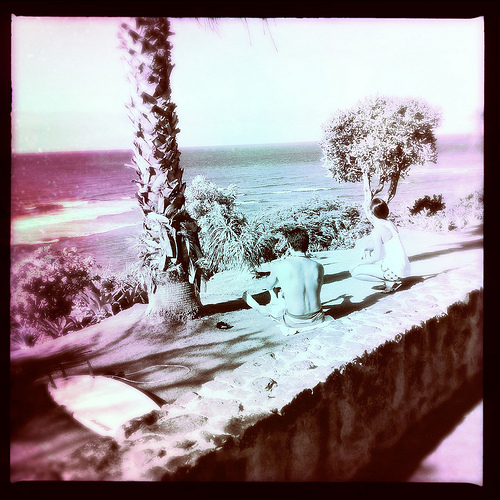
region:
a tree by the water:
[318, 83, 451, 294]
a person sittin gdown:
[236, 214, 411, 395]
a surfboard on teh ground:
[42, 333, 204, 493]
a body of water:
[14, 141, 121, 224]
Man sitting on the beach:
[238, 208, 331, 338]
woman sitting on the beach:
[347, 185, 416, 290]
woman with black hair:
[364, 188, 388, 217]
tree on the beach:
[306, 87, 436, 229]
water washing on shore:
[24, 188, 137, 260]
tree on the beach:
[130, 108, 220, 331]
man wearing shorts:
[274, 304, 322, 327]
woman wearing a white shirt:
[362, 216, 415, 282]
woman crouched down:
[346, 191, 416, 283]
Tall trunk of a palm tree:
[111, 17, 206, 342]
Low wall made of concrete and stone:
[21, 259, 482, 480]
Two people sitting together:
[241, 197, 410, 325]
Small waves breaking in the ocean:
[8, 196, 138, 243]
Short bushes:
[185, 175, 362, 270]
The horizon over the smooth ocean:
[175, 136, 317, 163]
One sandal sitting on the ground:
[212, 319, 235, 331]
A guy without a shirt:
[240, 227, 325, 329]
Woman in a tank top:
[351, 196, 411, 293]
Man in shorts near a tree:
[235, 225, 327, 327]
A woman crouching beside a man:
[346, 198, 408, 293]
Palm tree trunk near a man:
[123, 96, 202, 328]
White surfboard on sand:
[49, 364, 155, 432]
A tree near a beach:
[322, 98, 437, 206]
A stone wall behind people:
[20, 263, 482, 473]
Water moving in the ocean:
[11, 197, 134, 240]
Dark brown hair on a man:
[290, 225, 307, 252]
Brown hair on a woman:
[369, 195, 389, 219]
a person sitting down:
[272, 213, 321, 329]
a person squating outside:
[340, 175, 493, 317]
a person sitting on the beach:
[203, 219, 317, 366]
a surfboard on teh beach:
[61, 334, 208, 487]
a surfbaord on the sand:
[39, 368, 192, 496]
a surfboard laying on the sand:
[47, 330, 189, 497]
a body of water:
[176, 136, 271, 183]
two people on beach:
[271, 168, 443, 355]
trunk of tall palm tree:
[109, 31, 241, 355]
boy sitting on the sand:
[227, 218, 344, 365]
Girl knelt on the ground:
[341, 173, 416, 315]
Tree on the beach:
[306, 71, 451, 262]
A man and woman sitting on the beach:
[234, 187, 405, 381]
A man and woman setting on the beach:
[246, 191, 409, 338]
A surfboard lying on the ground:
[77, 363, 162, 449]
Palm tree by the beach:
[182, 179, 354, 280]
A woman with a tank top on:
[343, 212, 393, 314]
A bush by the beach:
[20, 240, 117, 360]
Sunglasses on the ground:
[209, 308, 241, 339]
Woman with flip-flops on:
[360, 265, 424, 302]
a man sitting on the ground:
[245, 224, 327, 320]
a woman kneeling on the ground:
[350, 189, 411, 291]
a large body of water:
[155, 127, 327, 191]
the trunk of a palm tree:
[105, 24, 200, 314]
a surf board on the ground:
[39, 355, 169, 443]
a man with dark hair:
[286, 225, 315, 254]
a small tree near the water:
[336, 97, 439, 218]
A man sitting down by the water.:
[244, 222, 328, 327]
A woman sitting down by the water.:
[344, 193, 413, 295]